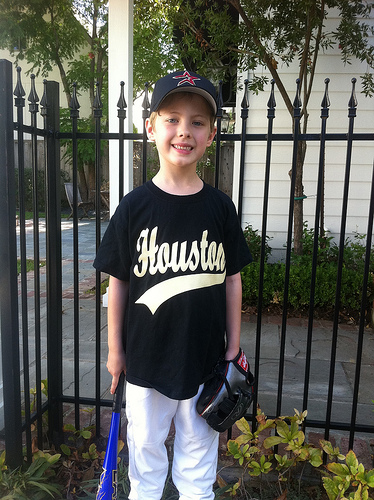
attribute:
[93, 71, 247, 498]
boy — young, smiling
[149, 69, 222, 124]
cap — red, black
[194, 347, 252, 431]
baseball glove — black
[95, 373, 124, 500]
baseball bat — blue, black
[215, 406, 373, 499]
plant — green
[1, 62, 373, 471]
fence — black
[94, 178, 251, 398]
shirt — black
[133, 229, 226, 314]
name — white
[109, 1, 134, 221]
pillar — white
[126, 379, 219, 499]
pants — white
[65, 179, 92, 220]
chair — deck 